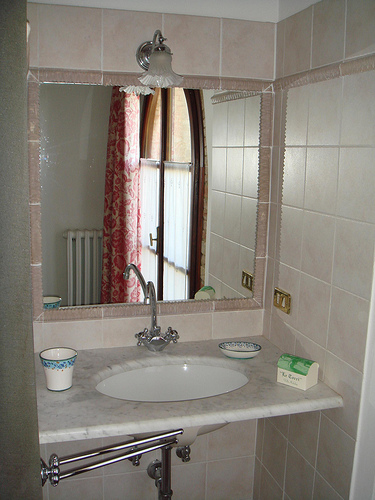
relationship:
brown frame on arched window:
[136, 90, 215, 287] [130, 84, 215, 296]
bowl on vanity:
[218, 340, 263, 360] [31, 306, 342, 408]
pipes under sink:
[145, 443, 181, 498] [92, 354, 255, 406]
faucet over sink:
[137, 279, 180, 353] [80, 346, 278, 428]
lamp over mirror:
[135, 29, 184, 89] [39, 80, 261, 308]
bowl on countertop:
[217, 340, 263, 360] [36, 347, 340, 445]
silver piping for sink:
[56, 445, 182, 495] [101, 343, 259, 405]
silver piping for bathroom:
[56, 445, 182, 495] [3, 3, 371, 498]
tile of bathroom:
[274, 80, 371, 392] [3, 3, 371, 498]